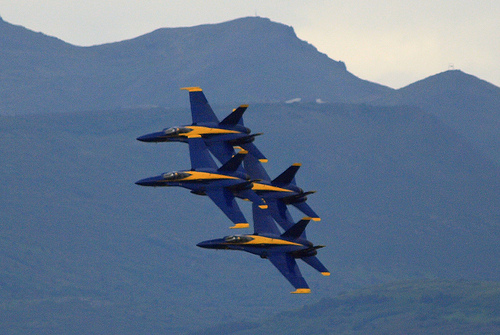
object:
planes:
[133, 86, 267, 172]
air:
[345, 152, 499, 335]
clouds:
[0, 0, 499, 90]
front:
[193, 238, 238, 252]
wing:
[267, 254, 310, 293]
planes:
[132, 132, 297, 228]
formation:
[133, 85, 331, 295]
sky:
[0, 0, 499, 93]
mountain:
[0, 101, 499, 334]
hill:
[390, 69, 498, 116]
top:
[210, 13, 303, 57]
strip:
[244, 234, 301, 249]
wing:
[177, 86, 222, 123]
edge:
[180, 85, 200, 127]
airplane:
[194, 202, 331, 295]